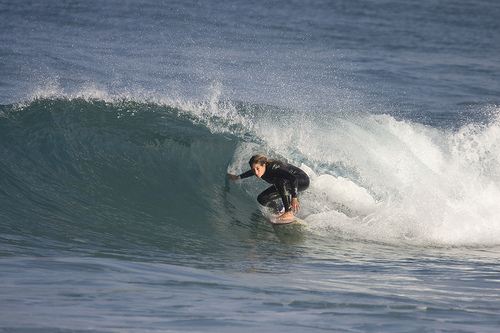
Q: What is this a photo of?
A: A surfer.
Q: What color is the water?
A: Blue.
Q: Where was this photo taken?
A: At the ocean.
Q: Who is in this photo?
A: A surfer.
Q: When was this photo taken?
A: In the daytime.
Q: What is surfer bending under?
A: A wave.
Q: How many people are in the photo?
A: One.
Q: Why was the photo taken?
A: To show surfing.